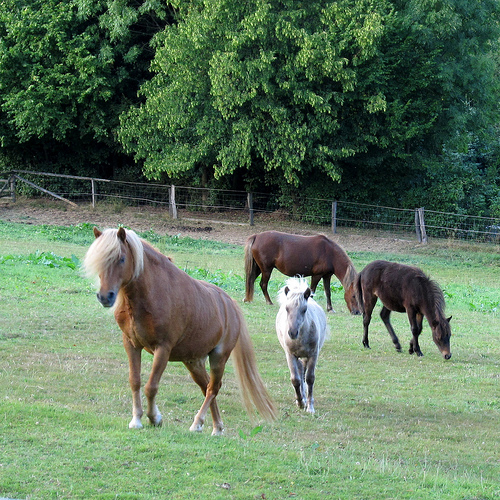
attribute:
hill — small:
[2, 383, 498, 495]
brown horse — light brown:
[80, 225, 279, 442]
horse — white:
[274, 275, 328, 415]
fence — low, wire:
[3, 167, 496, 254]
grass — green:
[4, 220, 496, 497]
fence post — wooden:
[331, 197, 336, 238]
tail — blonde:
[225, 299, 284, 432]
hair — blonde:
[78, 224, 145, 281]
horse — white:
[248, 262, 350, 403]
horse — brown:
[358, 252, 452, 359]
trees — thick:
[101, 4, 450, 238]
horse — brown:
[242, 211, 386, 318]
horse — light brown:
[61, 222, 253, 419]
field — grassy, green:
[3, 194, 495, 499]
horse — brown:
[239, 225, 364, 316]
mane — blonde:
[85, 224, 145, 289]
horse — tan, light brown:
[79, 222, 281, 435]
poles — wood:
[417, 204, 433, 242]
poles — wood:
[326, 202, 342, 231]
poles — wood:
[246, 190, 256, 224]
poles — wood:
[162, 182, 182, 218]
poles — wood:
[87, 177, 97, 204]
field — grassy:
[18, 242, 90, 493]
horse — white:
[265, 282, 357, 434]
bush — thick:
[188, 167, 497, 217]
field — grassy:
[19, 228, 89, 483]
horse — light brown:
[74, 223, 261, 456]